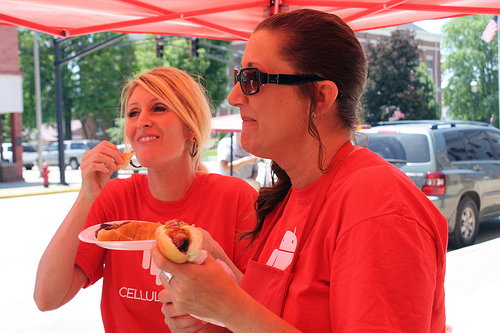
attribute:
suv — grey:
[344, 113, 499, 242]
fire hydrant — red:
[39, 159, 50, 187]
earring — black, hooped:
[186, 133, 207, 160]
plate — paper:
[61, 232, 134, 267]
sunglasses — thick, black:
[227, 65, 324, 95]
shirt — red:
[224, 138, 449, 331]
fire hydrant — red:
[35, 170, 68, 202]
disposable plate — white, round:
[85, 199, 207, 258]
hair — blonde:
[126, 56, 216, 143]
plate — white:
[69, 210, 169, 265]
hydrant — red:
[38, 160, 50, 188]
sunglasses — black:
[224, 65, 331, 109]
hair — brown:
[238, 9, 365, 247]